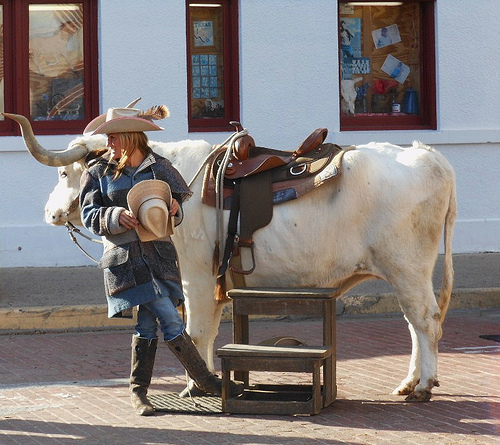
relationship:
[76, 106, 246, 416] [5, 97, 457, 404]
cowgirl by steer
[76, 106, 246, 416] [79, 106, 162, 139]
cowgirl with hat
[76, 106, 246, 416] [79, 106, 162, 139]
cowgirl wearing hat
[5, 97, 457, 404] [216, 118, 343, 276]
steer with saddle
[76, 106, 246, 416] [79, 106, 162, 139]
cowgirl holding hat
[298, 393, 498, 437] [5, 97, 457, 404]
shadow of steer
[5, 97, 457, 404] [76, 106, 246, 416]
steer and cowgirl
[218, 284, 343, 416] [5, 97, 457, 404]
stool by steer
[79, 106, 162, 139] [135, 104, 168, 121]
hat has feather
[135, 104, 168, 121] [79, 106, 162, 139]
feather in hat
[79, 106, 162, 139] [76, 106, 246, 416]
hat held by cowgirl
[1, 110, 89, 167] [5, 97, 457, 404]
horn on steer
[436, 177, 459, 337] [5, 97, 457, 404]
tail of steer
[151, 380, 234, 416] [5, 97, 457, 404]
grate under steer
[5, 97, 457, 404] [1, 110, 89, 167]
steer has horn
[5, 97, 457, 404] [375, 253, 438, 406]
steer has leg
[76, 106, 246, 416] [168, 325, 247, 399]
cowgirl wearing boot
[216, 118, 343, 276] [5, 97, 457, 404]
saddle on steer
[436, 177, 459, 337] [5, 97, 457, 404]
tail on steer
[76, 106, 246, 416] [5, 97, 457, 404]
cowgirl and steer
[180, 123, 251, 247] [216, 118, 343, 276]
rope on saddle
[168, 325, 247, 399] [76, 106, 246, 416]
boot on cowgirl